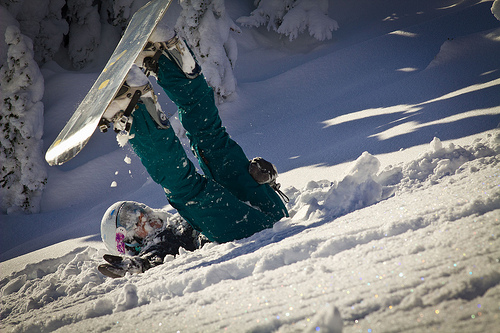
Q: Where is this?
A: This is at the field.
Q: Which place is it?
A: It is a field.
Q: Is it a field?
A: Yes, it is a field.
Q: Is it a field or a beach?
A: It is a field.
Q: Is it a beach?
A: No, it is a field.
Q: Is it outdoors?
A: Yes, it is outdoors.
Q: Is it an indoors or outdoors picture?
A: It is outdoors.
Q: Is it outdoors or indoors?
A: It is outdoors.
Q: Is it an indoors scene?
A: No, it is outdoors.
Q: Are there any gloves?
A: Yes, there are gloves.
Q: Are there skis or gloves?
A: Yes, there are gloves.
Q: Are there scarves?
A: No, there are no scarves.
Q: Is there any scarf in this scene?
A: No, there are no scarves.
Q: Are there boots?
A: Yes, there are boots.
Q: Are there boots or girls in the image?
A: Yes, there are boots.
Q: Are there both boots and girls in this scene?
A: No, there are boots but no girls.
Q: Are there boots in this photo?
A: Yes, there are boots.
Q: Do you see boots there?
A: Yes, there are boots.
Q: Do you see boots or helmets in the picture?
A: Yes, there are boots.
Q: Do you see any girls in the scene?
A: No, there are no girls.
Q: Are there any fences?
A: No, there are no fences.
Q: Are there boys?
A: No, there are no boys.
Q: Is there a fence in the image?
A: No, there are no fences.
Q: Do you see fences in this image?
A: No, there are no fences.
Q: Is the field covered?
A: Yes, the field is covered.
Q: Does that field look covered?
A: Yes, the field is covered.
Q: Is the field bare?
A: No, the field is covered.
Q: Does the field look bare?
A: No, the field is covered.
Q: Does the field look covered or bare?
A: The field is covered.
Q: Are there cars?
A: No, there are no cars.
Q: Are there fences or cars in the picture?
A: No, there are no cars or fences.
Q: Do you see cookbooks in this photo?
A: No, there are no cookbooks.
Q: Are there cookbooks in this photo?
A: No, there are no cookbooks.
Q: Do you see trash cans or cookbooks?
A: No, there are no cookbooks or trash cans.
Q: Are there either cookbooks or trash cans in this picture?
A: No, there are no cookbooks or trash cans.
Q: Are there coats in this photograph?
A: Yes, there is a coat.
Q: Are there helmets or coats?
A: Yes, there is a coat.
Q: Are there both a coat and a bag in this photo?
A: No, there is a coat but no bags.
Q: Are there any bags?
A: No, there are no bags.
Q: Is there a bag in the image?
A: No, there are no bags.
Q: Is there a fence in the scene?
A: No, there are no fences.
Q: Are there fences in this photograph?
A: No, there are no fences.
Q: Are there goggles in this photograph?
A: Yes, there are goggles.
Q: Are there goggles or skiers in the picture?
A: Yes, there are goggles.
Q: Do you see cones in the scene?
A: No, there are no cones.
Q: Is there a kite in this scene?
A: No, there are no kites.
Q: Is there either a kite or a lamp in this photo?
A: No, there are no kites or lamps.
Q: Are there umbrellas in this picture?
A: No, there are no umbrellas.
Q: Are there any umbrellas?
A: No, there are no umbrellas.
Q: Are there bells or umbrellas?
A: No, there are no umbrellas or bells.